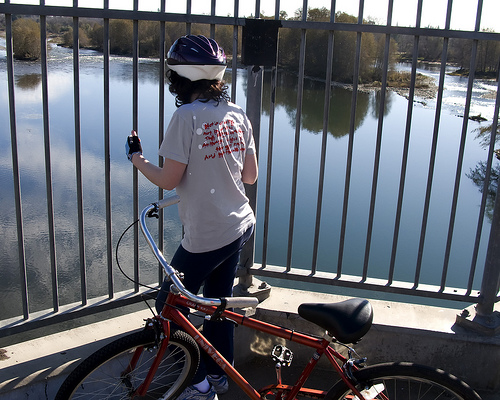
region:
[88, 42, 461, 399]
person looking out at the water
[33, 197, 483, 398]
red bike with silver handlebars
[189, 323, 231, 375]
writing on the side of the bike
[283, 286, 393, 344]
black bike seat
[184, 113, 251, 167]
red writing on the back of the shirt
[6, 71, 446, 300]
calm body of water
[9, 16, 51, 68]
tree growing in the water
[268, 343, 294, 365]
silver pedal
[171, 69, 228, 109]
hair sticking out of the back of the helmet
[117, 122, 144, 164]
black riding glove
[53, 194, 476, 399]
A red bicycle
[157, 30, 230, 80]
A back and white bicycle helmet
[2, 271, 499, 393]
Concrete base of a fence.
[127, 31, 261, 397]
A Female bicycle rider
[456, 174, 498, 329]
A thick metal pole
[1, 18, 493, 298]
A tall black metal fence.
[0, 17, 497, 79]
Trees in the background.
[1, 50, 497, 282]
A large body of water.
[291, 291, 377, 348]
A black bicycle seat.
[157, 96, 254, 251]
A white t-shirt with red writing.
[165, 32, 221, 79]
the helmet on the person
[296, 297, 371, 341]
the black seat on the bike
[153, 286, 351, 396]
the red frame of the bike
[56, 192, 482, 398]
the red bike behind the boy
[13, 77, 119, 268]
the water beyond the gate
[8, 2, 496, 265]
the metal gate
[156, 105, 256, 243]
the short sleeved shirt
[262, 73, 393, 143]
the reflection on the water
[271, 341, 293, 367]
the pedal on the bike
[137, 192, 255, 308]
the handles on the bike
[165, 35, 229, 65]
Blue helmet on a girl's head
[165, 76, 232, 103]
Girl's dark curly hair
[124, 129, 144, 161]
Glove on girl's left hand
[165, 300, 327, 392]
Red body of a bicycle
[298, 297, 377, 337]
Black seat on a bicycle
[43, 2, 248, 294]
Metal fence in front of water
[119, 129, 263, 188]
Girl gripping a hand rail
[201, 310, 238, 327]
Black break handle on a bicycle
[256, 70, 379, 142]
Tree's reflecting in the water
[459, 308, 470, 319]
Bolt holding on a metal railing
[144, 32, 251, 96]
woman wearing a helmet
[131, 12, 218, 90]
woman wearing a helmet